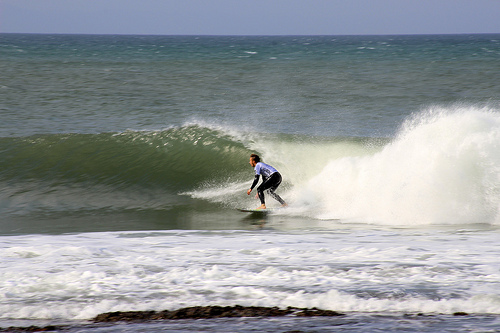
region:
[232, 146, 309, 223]
surfer in the ocean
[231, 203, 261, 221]
front of a surfboard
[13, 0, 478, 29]
blue sky in the distance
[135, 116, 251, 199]
wave rolling from the ocean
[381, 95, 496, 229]
waves crashing in the ocean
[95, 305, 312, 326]
rocks in the water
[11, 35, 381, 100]
water of an ocean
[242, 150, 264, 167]
face of a surfer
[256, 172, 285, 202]
black pants of a surfer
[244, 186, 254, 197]
left hand of a surfer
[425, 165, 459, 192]
part of a splash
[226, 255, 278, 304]
part of a water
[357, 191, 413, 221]
edge of a splash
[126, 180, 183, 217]
part of a water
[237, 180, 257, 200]
part of a hand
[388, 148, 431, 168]
part of a splash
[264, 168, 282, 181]
part of a costume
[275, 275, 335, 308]
part of a water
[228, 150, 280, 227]
man surfing on waves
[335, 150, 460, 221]
white waves riding in back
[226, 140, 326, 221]
man is surfing hard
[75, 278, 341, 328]
rocks in near vision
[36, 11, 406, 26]
blue sky in distance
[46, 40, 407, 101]
waves in background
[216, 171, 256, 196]
left hand of surfer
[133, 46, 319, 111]
waves in distance in back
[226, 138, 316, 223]
surfer with blue suit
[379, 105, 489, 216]
white waves are rising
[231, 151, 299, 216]
surfer is in the ocean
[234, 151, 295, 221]
surfer wears a purple shirt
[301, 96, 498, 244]
splash of water formed behind the surfer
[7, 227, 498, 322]
the water is foamy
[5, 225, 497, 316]
foamy water is white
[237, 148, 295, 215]
surfer wears a wet suit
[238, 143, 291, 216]
surfer is bare feet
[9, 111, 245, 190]
a wave is rolling in the ocean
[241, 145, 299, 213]
man has black hair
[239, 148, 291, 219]
the hands of guy is in front of him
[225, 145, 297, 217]
surfer in front of wave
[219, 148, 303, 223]
surfer in a blue shirt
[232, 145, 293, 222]
surfer in black pants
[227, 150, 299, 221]
man on a surfboard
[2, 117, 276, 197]
wave breaking in front of man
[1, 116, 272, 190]
wave breaking in front of surfer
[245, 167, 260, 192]
left arm of surfer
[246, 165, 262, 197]
left arm of a man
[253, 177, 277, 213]
left leg of surfer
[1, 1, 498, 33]
sky in the distance